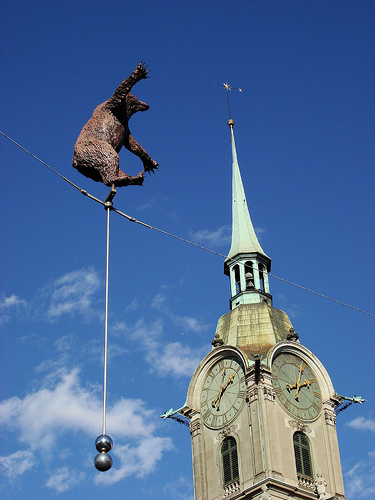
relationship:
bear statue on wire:
[71, 61, 160, 186] [82, 192, 87, 193]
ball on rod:
[94, 450, 110, 473] [103, 379, 107, 384]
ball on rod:
[96, 435, 113, 449] [103, 379, 107, 384]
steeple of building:
[221, 79, 275, 307] [159, 81, 367, 500]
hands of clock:
[288, 363, 312, 402] [271, 353, 324, 421]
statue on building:
[313, 475, 332, 498] [160, 108, 362, 497]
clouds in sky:
[10, 397, 100, 429] [281, 116, 283, 124]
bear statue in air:
[71, 61, 160, 186] [315, 138, 316, 143]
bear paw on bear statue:
[133, 63, 147, 80] [71, 61, 160, 186]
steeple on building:
[213, 79, 271, 301] [159, 81, 367, 500]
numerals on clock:
[198, 359, 245, 425] [199, 357, 248, 428]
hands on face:
[210, 367, 235, 411] [200, 360, 245, 428]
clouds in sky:
[7, 263, 213, 497] [4, 10, 363, 490]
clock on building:
[199, 357, 248, 428] [160, 108, 362, 497]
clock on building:
[271, 353, 324, 421] [160, 108, 362, 497]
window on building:
[218, 433, 246, 498] [162, 155, 363, 488]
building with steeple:
[159, 81, 367, 500] [207, 81, 271, 307]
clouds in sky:
[6, 220, 363, 494] [4, 10, 363, 490]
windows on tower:
[219, 429, 313, 493] [155, 81, 357, 497]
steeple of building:
[213, 79, 271, 301] [159, 81, 367, 500]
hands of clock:
[210, 364, 234, 410] [199, 357, 248, 428]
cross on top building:
[214, 81, 241, 119] [159, 81, 367, 500]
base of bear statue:
[102, 184, 115, 209] [71, 61, 160, 186]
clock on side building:
[199, 357, 248, 428] [160, 108, 362, 497]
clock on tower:
[199, 357, 248, 428] [157, 318, 348, 480]